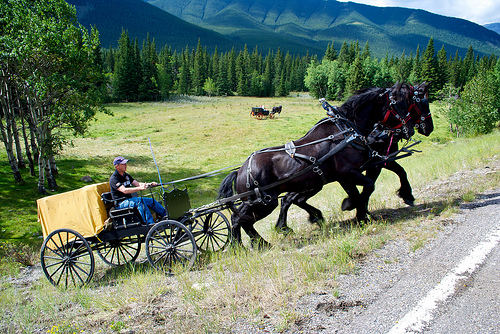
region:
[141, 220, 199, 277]
the wheel of a cart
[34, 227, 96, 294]
the wheel of a cart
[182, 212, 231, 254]
the wheel of a cart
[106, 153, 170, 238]
a man driving a cart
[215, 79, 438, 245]
horses pulling a cart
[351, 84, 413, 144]
the head of a horse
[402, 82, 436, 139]
the head of a horse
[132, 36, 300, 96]
a group of green trees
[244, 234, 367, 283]
patchy grass on the side of the road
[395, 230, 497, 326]
old street paint on the road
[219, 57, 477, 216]
two horses in photo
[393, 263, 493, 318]
street next to the grass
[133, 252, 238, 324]
grass on the ground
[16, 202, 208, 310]
wheels on the carriage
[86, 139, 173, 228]
one man in a carriage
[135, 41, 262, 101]
trees in the distance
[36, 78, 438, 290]
Horses pulling a wagon up a slope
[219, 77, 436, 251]
Two black horses straining to climb a slope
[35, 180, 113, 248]
Yellow tarp on the back of a wagon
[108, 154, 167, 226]
Man holding reins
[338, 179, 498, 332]
Edge of a street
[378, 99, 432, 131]
Two red briddles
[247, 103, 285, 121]
Horse and carraige on a flat grass field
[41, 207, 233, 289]
Four large wagon wheels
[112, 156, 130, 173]
Blue baseball cap on a person's head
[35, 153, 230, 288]
Man in a wagon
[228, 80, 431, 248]
two dark horses walking uphill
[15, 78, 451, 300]
one horse drawn carriage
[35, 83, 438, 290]
two horses pulling one carriage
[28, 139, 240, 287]
one man sitting on carriage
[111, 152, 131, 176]
one man wearing blue baseball cap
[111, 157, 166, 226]
one man wearing blue jeans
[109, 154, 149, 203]
one man wearing dark short sleeved shirt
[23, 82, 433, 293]
one horse drawn carriage going uphill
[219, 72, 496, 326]
horses next to gray lined pavement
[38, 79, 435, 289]
Horses pulling a wagon.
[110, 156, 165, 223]
A man sitting in a wagon.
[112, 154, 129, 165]
The man's blue hat.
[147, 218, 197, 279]
The front wagon wheel.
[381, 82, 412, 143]
The head of the horse.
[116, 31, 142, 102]
A large green tree.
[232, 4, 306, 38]
Part of a hill in the distance.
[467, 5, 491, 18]
Part of the sky.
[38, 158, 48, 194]
Part of the trunk of the tree.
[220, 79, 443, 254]
pair of black horses pulling carriage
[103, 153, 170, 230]
man sitting on carriage in blue jeans and cap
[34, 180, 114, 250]
yellow covered box on carriage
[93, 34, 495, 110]
green evergreen trees in background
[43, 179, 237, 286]
old fashioned four wheeled carriage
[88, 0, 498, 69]
expansive mountain range in distance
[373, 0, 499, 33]
light blue sky with white clouds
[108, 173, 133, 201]
blue tee shirt on man in carriage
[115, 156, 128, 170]
blue baseball cap on man in carriage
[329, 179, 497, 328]
edge of gray concrete road with white line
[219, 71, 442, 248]
a pair of horses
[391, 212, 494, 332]
line on the road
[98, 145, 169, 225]
man on a carriage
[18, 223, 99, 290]
back wheel on the carriage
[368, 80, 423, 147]
bridle on the horse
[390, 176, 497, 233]
shadow on the ground